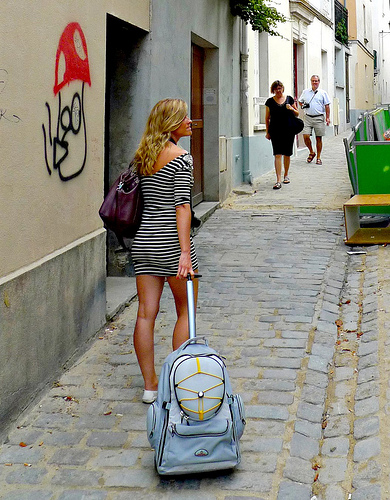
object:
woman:
[98, 97, 203, 407]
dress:
[131, 151, 202, 278]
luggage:
[144, 273, 248, 483]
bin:
[343, 104, 390, 223]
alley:
[1, 98, 389, 499]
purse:
[99, 153, 144, 239]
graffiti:
[42, 21, 92, 183]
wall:
[0, 0, 149, 443]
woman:
[263, 79, 304, 191]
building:
[149, 0, 235, 223]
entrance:
[190, 37, 205, 207]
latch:
[197, 392, 205, 400]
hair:
[132, 97, 188, 179]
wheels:
[156, 468, 172, 484]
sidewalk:
[1, 125, 390, 499]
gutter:
[280, 241, 377, 498]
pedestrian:
[299, 69, 333, 166]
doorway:
[293, 39, 303, 148]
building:
[241, 0, 336, 183]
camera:
[300, 100, 311, 112]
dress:
[263, 95, 298, 156]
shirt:
[297, 85, 330, 117]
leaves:
[242, 0, 253, 9]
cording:
[173, 354, 225, 423]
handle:
[182, 269, 202, 345]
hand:
[286, 103, 293, 112]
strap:
[287, 94, 295, 116]